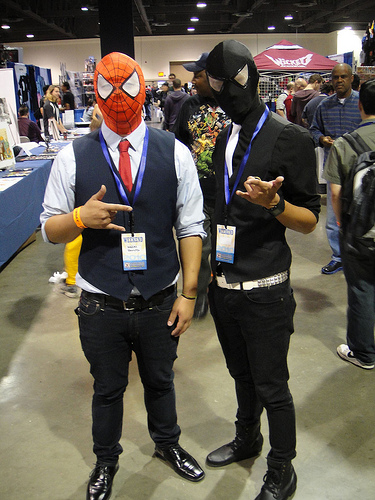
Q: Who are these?
A: People.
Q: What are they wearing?
A: Masks.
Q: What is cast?
A: Shadow.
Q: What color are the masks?
A: Red and black.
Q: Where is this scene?
A: At a convention.